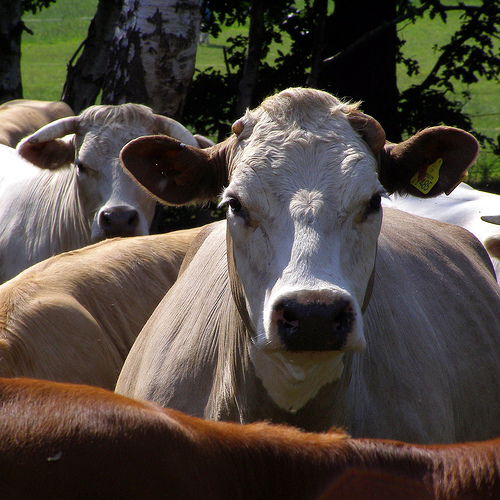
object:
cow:
[114, 87, 500, 441]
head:
[117, 86, 482, 383]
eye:
[218, 189, 249, 227]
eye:
[360, 190, 383, 216]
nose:
[274, 291, 356, 351]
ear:
[119, 134, 229, 207]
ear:
[383, 125, 480, 199]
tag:
[409, 158, 443, 196]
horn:
[230, 119, 256, 139]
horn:
[345, 108, 386, 153]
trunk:
[102, 1, 196, 124]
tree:
[295, 7, 500, 189]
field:
[0, 0, 500, 193]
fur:
[114, 88, 493, 433]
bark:
[102, 3, 196, 116]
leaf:
[407, 65, 416, 78]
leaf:
[443, 77, 455, 94]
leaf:
[477, 32, 492, 47]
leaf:
[486, 133, 496, 152]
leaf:
[436, 11, 449, 23]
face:
[223, 105, 384, 354]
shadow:
[231, 189, 296, 341]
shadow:
[339, 220, 378, 304]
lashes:
[215, 194, 237, 211]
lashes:
[371, 186, 393, 203]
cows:
[0, 217, 208, 391]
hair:
[255, 85, 364, 131]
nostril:
[277, 304, 300, 330]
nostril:
[326, 304, 349, 330]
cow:
[0, 94, 216, 281]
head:
[26, 106, 216, 244]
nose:
[100, 205, 141, 234]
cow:
[1, 377, 500, 499]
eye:
[75, 159, 95, 179]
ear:
[16, 137, 76, 171]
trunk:
[331, 0, 401, 144]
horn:
[16, 116, 83, 156]